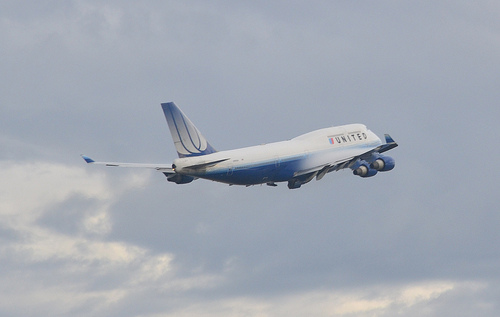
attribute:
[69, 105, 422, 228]
plane — united airlines, in flight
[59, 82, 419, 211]
plane — white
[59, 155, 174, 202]
tail — grey, blue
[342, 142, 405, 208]
engines — blue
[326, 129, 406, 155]
letters — black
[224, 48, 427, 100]
sky — overcast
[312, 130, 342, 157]
symbol — red, blue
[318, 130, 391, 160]
windows — side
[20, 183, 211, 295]
clouds — grey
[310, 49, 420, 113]
sky — clear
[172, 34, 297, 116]
sky — clear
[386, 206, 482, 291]
sky — clear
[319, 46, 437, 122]
sky — clear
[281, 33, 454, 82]
sky — clear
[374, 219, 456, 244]
sky — clear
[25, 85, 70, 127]
sky — clear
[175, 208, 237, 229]
sky — clear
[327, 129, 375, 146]
word — United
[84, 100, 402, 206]
plane — blue, white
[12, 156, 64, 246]
clouds — white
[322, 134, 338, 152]
symbol — united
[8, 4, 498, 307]
sky — clear